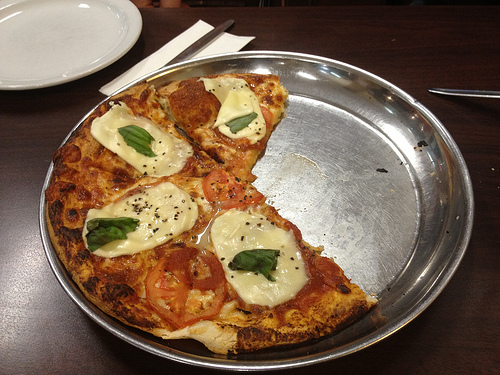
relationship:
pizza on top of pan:
[42, 73, 378, 356] [44, 54, 477, 373]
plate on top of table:
[0, 1, 147, 92] [13, 21, 495, 371]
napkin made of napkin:
[96, 10, 261, 99] [99, 19, 255, 96]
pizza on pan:
[52, 75, 361, 338] [44, 54, 477, 373]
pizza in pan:
[52, 75, 361, 338] [44, 54, 477, 373]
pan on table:
[44, 54, 477, 373] [13, 21, 495, 371]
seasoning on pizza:
[131, 193, 154, 219] [43, 77, 357, 358]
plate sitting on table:
[0, 1, 143, 92] [13, 21, 495, 371]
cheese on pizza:
[115, 180, 199, 235] [81, 64, 385, 356]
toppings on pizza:
[70, 165, 251, 252] [42, 60, 404, 340]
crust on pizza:
[236, 71, 281, 81] [42, 73, 378, 356]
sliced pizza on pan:
[40, 65, 374, 342] [44, 54, 477, 373]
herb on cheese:
[232, 246, 281, 280] [213, 208, 301, 303]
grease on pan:
[282, 152, 332, 187] [266, 78, 493, 332]